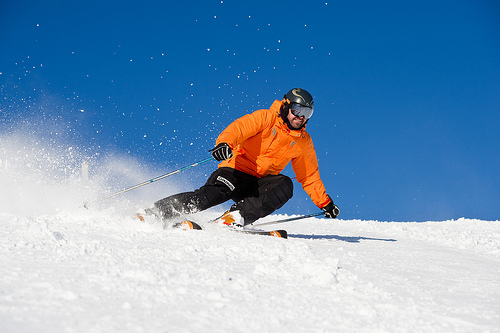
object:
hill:
[2, 209, 499, 332]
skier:
[136, 87, 339, 226]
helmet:
[284, 88, 315, 109]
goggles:
[281, 95, 314, 120]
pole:
[253, 209, 332, 229]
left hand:
[321, 202, 341, 219]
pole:
[83, 154, 220, 212]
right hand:
[207, 142, 233, 160]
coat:
[215, 100, 333, 211]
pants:
[153, 167, 293, 225]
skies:
[209, 214, 288, 239]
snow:
[4, 210, 496, 328]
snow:
[4, 101, 193, 193]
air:
[4, 9, 493, 215]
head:
[280, 87, 314, 131]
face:
[286, 109, 311, 129]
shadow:
[286, 233, 400, 245]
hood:
[270, 99, 284, 114]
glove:
[210, 142, 230, 161]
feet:
[136, 209, 201, 230]